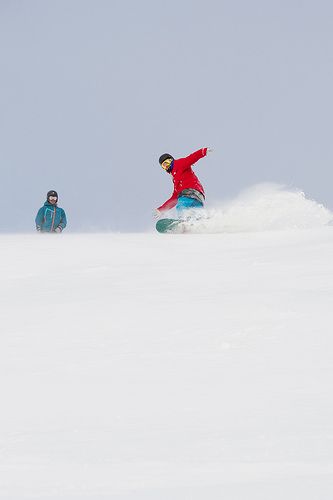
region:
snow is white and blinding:
[61, 301, 311, 472]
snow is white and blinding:
[15, 277, 209, 374]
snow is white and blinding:
[55, 304, 161, 379]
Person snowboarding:
[149, 142, 220, 236]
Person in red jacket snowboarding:
[149, 142, 219, 235]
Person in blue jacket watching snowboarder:
[32, 186, 70, 237]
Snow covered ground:
[2, 232, 331, 497]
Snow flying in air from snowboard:
[182, 180, 331, 234]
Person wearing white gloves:
[149, 144, 219, 218]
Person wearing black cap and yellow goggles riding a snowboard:
[149, 143, 224, 239]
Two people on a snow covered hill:
[33, 142, 215, 242]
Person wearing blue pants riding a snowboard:
[152, 141, 219, 236]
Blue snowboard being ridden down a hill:
[152, 216, 215, 235]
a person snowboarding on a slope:
[153, 144, 215, 233]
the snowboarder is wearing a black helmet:
[157, 150, 172, 169]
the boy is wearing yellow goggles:
[158, 155, 172, 167]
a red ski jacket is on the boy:
[155, 146, 207, 210]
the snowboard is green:
[153, 212, 205, 235]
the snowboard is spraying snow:
[152, 144, 328, 237]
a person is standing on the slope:
[32, 186, 71, 238]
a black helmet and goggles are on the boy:
[44, 187, 56, 202]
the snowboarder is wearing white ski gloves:
[150, 145, 212, 213]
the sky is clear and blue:
[5, 3, 331, 234]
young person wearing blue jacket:
[23, 175, 73, 240]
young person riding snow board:
[141, 143, 227, 250]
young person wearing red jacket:
[148, 149, 221, 199]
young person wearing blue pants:
[142, 182, 216, 239]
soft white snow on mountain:
[9, 363, 138, 498]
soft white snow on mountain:
[158, 274, 305, 425]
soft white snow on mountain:
[82, 254, 297, 374]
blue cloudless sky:
[17, 17, 193, 117]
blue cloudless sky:
[158, 18, 319, 120]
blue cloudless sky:
[69, 91, 147, 209]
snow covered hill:
[168, 429, 187, 453]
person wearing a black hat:
[152, 152, 187, 175]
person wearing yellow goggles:
[157, 153, 177, 176]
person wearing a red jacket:
[157, 143, 208, 198]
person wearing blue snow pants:
[182, 193, 208, 234]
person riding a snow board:
[143, 152, 213, 226]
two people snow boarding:
[32, 133, 267, 249]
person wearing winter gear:
[152, 148, 211, 233]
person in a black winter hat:
[34, 189, 84, 242]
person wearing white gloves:
[156, 137, 214, 206]